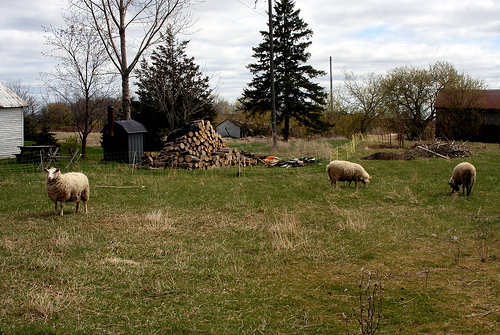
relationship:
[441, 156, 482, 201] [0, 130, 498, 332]
sheep eating grass